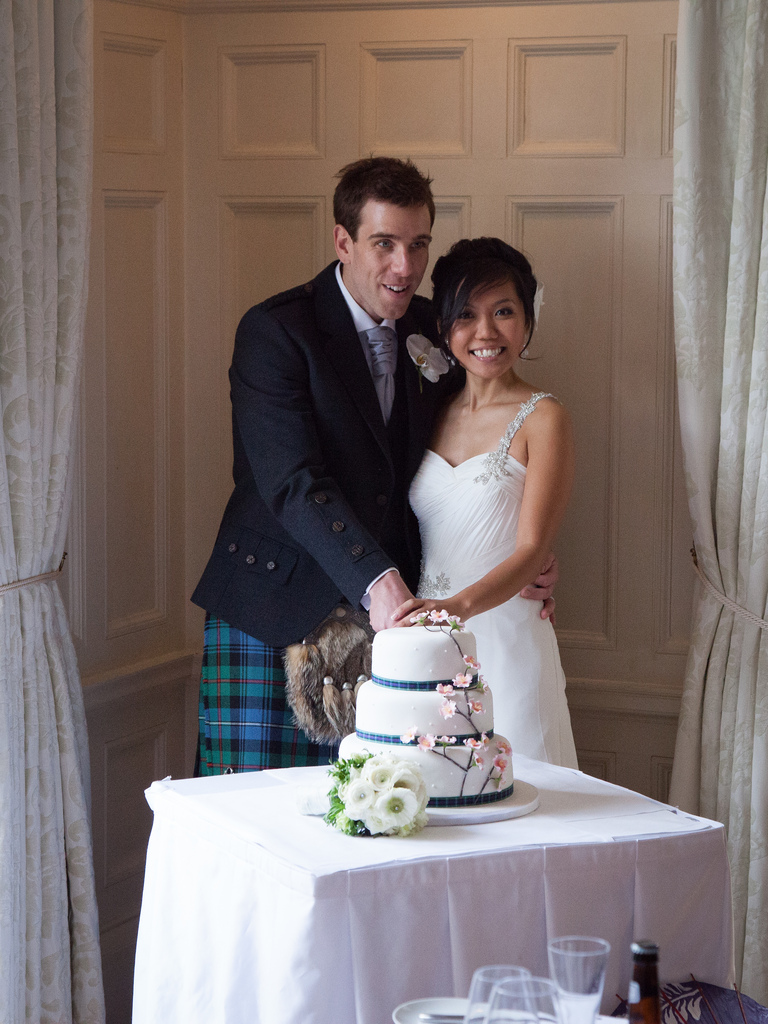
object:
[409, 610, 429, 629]
flower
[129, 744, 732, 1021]
cloth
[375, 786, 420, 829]
flower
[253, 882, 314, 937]
light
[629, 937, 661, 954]
opener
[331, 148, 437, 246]
hair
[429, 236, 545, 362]
hair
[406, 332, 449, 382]
flower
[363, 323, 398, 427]
tie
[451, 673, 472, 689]
flower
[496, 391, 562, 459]
strap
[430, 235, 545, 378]
head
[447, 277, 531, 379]
face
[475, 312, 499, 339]
nose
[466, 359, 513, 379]
chin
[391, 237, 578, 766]
woman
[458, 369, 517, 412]
neck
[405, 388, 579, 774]
dress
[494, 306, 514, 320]
eye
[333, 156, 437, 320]
head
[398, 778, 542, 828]
tray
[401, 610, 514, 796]
flowers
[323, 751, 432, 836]
bouquet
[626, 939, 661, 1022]
bottle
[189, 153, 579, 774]
couple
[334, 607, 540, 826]
cake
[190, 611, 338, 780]
kilt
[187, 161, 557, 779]
groom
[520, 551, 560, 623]
arm